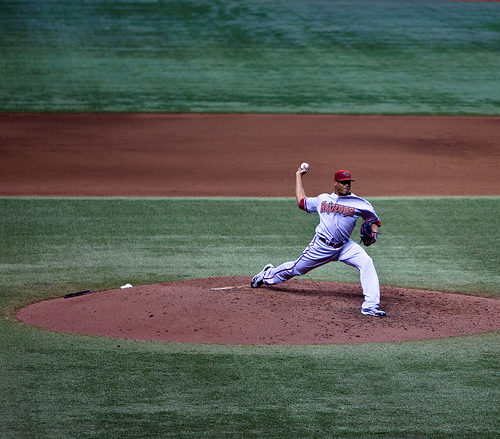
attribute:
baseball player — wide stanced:
[254, 163, 385, 319]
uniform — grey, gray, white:
[264, 193, 380, 307]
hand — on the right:
[296, 165, 307, 171]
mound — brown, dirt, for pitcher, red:
[17, 275, 499, 343]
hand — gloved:
[359, 221, 379, 244]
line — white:
[210, 280, 251, 291]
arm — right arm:
[292, 168, 317, 211]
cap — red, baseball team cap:
[335, 171, 355, 184]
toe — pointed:
[250, 277, 261, 290]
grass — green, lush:
[2, 2, 499, 436]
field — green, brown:
[1, 2, 500, 437]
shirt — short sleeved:
[306, 192, 379, 241]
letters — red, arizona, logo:
[320, 199, 355, 218]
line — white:
[1, 190, 499, 202]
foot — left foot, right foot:
[358, 303, 385, 320]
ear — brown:
[333, 180, 339, 188]